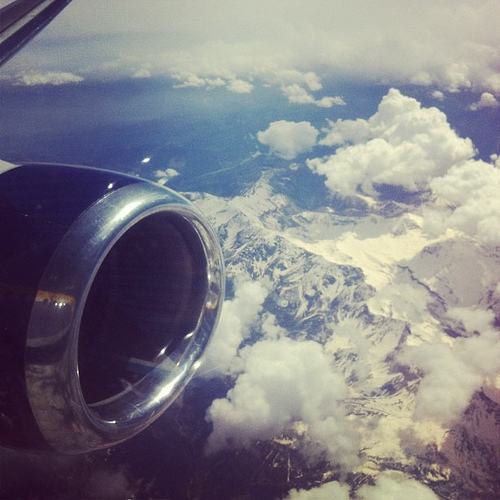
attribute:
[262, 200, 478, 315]
snowy valley — below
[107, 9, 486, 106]
skys — cloudy, white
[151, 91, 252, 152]
forest — area, wooded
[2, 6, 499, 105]
cloud — heavy, white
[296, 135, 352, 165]
wall — thin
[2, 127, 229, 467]
engine — shiny, plane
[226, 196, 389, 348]
mountain — massive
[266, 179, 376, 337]
mountain top — black, white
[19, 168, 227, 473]
trim — chrome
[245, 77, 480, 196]
clouds — white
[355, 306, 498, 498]
mountain — peaks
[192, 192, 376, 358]
mountain — peaks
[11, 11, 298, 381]
plane — wing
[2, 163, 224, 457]
engine — airplane, silver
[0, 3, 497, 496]
clouds — white, fluffy